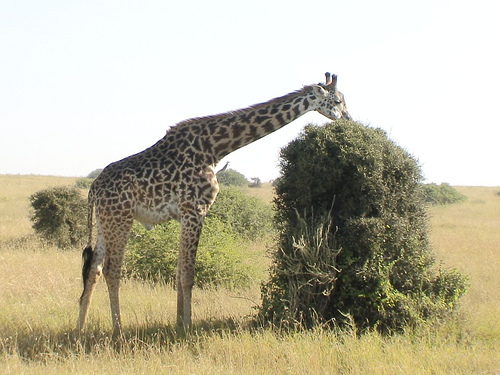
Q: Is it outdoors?
A: Yes, it is outdoors.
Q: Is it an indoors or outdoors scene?
A: It is outdoors.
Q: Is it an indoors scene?
A: No, it is outdoors.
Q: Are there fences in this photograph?
A: No, there are no fences.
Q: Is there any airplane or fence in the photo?
A: No, there are no fences or airplanes.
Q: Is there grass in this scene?
A: Yes, there is grass.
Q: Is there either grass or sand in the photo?
A: Yes, there is grass.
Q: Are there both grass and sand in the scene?
A: No, there is grass but no sand.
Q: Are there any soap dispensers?
A: No, there are no soap dispensers.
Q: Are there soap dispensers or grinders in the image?
A: No, there are no soap dispensers or grinders.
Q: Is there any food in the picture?
A: Yes, there is food.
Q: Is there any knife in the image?
A: No, there are no knives.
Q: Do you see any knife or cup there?
A: No, there are no knives or cups.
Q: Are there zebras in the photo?
A: No, there are no zebras.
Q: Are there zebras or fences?
A: No, there are no zebras or fences.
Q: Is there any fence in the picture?
A: No, there are no fences.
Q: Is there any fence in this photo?
A: No, there are no fences.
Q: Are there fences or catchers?
A: No, there are no fences or catchers.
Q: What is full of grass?
A: The field is full of grass.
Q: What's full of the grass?
A: The field is full of grass.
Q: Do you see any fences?
A: No, there are no fences.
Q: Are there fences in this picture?
A: No, there are no fences.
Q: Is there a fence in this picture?
A: No, there are no fences.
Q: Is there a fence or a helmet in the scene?
A: No, there are no fences or helmets.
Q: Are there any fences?
A: No, there are no fences.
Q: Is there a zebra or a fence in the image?
A: No, there are no fences or zebras.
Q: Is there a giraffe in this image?
A: Yes, there is a giraffe.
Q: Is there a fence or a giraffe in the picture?
A: Yes, there is a giraffe.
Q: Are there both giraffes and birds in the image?
A: No, there is a giraffe but no birds.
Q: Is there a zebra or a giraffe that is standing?
A: Yes, the giraffe is standing.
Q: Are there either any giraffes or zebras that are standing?
A: Yes, the giraffe is standing.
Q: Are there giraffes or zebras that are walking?
A: Yes, the giraffe is walking.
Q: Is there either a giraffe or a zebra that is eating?
A: Yes, the giraffe is eating.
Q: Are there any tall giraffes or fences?
A: Yes, there is a tall giraffe.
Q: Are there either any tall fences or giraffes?
A: Yes, there is a tall giraffe.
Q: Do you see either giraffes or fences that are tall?
A: Yes, the giraffe is tall.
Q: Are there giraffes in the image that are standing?
A: Yes, there is a giraffe that is standing.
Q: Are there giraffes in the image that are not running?
A: Yes, there is a giraffe that is standing.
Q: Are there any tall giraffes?
A: Yes, there is a tall giraffe.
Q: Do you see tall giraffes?
A: Yes, there is a tall giraffe.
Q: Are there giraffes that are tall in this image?
A: Yes, there is a tall giraffe.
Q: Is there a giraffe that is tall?
A: Yes, there is a giraffe that is tall.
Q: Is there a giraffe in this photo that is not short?
A: Yes, there is a tall giraffe.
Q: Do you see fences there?
A: No, there are no fences.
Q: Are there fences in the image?
A: No, there are no fences.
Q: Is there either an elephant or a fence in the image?
A: No, there are no fences or elephants.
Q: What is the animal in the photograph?
A: The animal is a giraffe.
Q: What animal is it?
A: The animal is a giraffe.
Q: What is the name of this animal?
A: This is a giraffe.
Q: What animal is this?
A: This is a giraffe.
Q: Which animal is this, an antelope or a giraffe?
A: This is a giraffe.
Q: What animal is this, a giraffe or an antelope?
A: This is a giraffe.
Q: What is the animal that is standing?
A: The animal is a giraffe.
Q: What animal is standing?
A: The animal is a giraffe.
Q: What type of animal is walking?
A: The animal is a giraffe.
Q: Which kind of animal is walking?
A: The animal is a giraffe.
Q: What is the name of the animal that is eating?
A: The animal is a giraffe.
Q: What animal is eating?
A: The animal is a giraffe.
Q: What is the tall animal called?
A: The animal is a giraffe.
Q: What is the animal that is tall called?
A: The animal is a giraffe.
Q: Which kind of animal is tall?
A: The animal is a giraffe.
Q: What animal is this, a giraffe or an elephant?
A: This is a giraffe.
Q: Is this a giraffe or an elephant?
A: This is a giraffe.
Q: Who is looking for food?
A: The giraffe is looking for food.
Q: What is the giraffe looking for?
A: The giraffe is looking for food.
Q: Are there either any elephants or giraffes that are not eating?
A: No, there is a giraffe but it is eating.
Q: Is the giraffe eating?
A: Yes, the giraffe is eating.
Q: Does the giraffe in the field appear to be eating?
A: Yes, the giraffe is eating.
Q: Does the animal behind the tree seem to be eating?
A: Yes, the giraffe is eating.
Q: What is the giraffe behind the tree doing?
A: The giraffe is eating.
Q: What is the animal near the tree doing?
A: The giraffe is eating.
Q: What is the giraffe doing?
A: The giraffe is eating.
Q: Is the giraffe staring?
A: No, the giraffe is eating.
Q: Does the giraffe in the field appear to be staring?
A: No, the giraffe is eating.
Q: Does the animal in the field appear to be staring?
A: No, the giraffe is eating.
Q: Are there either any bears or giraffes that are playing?
A: No, there is a giraffe but it is eating.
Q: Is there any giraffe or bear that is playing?
A: No, there is a giraffe but it is eating.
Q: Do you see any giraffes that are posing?
A: No, there is a giraffe but it is eating.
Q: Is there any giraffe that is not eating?
A: No, there is a giraffe but it is eating.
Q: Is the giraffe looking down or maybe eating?
A: The giraffe is eating.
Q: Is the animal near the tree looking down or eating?
A: The giraffe is eating.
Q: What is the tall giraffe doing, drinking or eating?
A: The giraffe is eating.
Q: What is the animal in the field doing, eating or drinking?
A: The giraffe is eating.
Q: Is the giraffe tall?
A: Yes, the giraffe is tall.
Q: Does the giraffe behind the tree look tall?
A: Yes, the giraffe is tall.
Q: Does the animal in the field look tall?
A: Yes, the giraffe is tall.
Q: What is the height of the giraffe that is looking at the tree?
A: The giraffe is tall.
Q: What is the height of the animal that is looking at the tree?
A: The giraffe is tall.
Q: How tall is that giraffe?
A: The giraffe is tall.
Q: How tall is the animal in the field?
A: The giraffe is tall.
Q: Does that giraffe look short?
A: No, the giraffe is tall.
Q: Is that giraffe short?
A: No, the giraffe is tall.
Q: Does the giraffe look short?
A: No, the giraffe is tall.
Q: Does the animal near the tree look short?
A: No, the giraffe is tall.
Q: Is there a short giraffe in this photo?
A: No, there is a giraffe but it is tall.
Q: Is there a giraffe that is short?
A: No, there is a giraffe but it is tall.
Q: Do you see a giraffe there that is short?
A: No, there is a giraffe but it is tall.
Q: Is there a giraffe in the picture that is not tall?
A: No, there is a giraffe but it is tall.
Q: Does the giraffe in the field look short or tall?
A: The giraffe is tall.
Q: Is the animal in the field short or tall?
A: The giraffe is tall.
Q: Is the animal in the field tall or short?
A: The giraffe is tall.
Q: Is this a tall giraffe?
A: Yes, this is a tall giraffe.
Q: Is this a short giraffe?
A: No, this is a tall giraffe.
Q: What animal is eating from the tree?
A: The animal is a giraffe.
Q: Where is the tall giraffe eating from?
A: The giraffe is eating from the tree.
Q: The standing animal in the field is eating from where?
A: The giraffe is eating from the tree.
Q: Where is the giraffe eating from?
A: The giraffe is eating from the tree.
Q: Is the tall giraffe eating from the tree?
A: Yes, the giraffe is eating from the tree.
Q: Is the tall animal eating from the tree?
A: Yes, the giraffe is eating from the tree.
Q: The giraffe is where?
A: The giraffe is in the field.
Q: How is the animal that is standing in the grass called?
A: The animal is a giraffe.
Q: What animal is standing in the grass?
A: The animal is a giraffe.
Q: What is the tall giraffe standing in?
A: The giraffe is standing in the grass.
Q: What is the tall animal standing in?
A: The giraffe is standing in the grass.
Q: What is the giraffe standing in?
A: The giraffe is standing in the grass.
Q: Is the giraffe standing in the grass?
A: Yes, the giraffe is standing in the grass.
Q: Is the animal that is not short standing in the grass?
A: Yes, the giraffe is standing in the grass.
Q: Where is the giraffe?
A: The giraffe is in the field.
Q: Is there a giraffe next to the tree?
A: Yes, there is a giraffe next to the tree.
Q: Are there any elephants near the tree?
A: No, there is a giraffe near the tree.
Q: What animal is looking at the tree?
A: The giraffe is looking at the tree.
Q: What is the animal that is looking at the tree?
A: The animal is a giraffe.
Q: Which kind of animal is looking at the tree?
A: The animal is a giraffe.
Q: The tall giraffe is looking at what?
A: The giraffe is looking at the tree.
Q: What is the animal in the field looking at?
A: The giraffe is looking at the tree.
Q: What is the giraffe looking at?
A: The giraffe is looking at the tree.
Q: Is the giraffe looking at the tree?
A: Yes, the giraffe is looking at the tree.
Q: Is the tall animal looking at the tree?
A: Yes, the giraffe is looking at the tree.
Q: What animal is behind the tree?
A: The animal is a giraffe.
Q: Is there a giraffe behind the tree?
A: Yes, there is a giraffe behind the tree.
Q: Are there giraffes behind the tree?
A: Yes, there is a giraffe behind the tree.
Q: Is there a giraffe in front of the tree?
A: No, the giraffe is behind the tree.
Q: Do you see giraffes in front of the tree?
A: No, the giraffe is behind the tree.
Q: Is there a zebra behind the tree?
A: No, there is a giraffe behind the tree.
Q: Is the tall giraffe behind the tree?
A: Yes, the giraffe is behind the tree.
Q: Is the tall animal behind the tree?
A: Yes, the giraffe is behind the tree.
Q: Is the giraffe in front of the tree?
A: No, the giraffe is behind the tree.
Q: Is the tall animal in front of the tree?
A: No, the giraffe is behind the tree.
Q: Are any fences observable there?
A: No, there are no fences.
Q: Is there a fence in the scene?
A: No, there are no fences.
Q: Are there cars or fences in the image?
A: No, there are no fences or cars.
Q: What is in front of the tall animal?
A: The tree is in front of the giraffe.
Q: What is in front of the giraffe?
A: The tree is in front of the giraffe.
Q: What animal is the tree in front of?
A: The tree is in front of the giraffe.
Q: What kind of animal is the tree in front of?
A: The tree is in front of the giraffe.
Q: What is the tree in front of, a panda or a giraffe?
A: The tree is in front of a giraffe.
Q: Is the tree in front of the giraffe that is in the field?
A: Yes, the tree is in front of the giraffe.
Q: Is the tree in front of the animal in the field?
A: Yes, the tree is in front of the giraffe.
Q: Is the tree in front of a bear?
A: No, the tree is in front of the giraffe.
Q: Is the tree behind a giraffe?
A: No, the tree is in front of a giraffe.